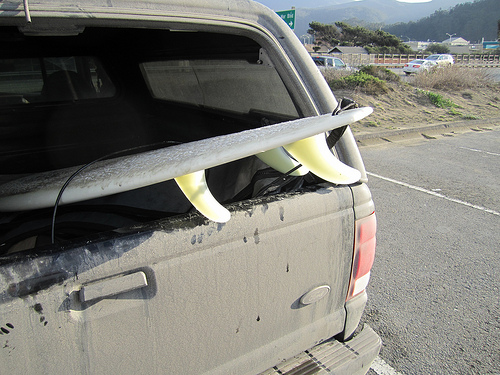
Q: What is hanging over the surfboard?
A: A cord.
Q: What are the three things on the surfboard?
A: Fins.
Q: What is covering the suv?
A: Dirt.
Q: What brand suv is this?
A: Ford.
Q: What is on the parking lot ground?
A: White line.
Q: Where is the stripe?
A: In the parking lot.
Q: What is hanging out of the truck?
A: Surfboard.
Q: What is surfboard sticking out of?
A: Back window.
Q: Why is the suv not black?
A: Dirt.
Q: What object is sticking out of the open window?
A: Surfboard.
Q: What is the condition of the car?
A: Dirty.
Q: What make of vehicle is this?
A: Ford.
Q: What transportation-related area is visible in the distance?
A: Roadway.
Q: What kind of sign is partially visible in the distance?
A: Roadway exit marker.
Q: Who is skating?
A: No one.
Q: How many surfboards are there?
A: 1.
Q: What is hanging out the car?
A: Surfboard.